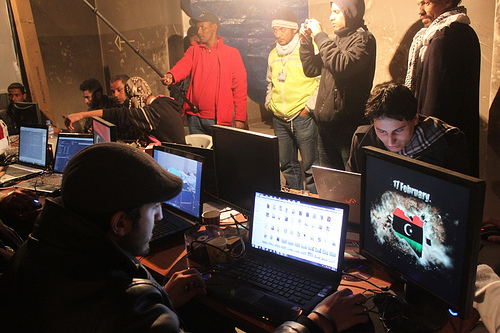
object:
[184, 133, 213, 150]
chair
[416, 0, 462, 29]
head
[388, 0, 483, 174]
person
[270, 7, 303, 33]
hat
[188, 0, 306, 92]
artwork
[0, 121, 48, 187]
laptop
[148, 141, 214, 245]
laptop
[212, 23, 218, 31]
ear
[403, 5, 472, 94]
scarf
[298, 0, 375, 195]
man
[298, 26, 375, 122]
sweater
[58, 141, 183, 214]
dark hat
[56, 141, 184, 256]
head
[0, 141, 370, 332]
man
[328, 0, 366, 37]
hat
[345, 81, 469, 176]
man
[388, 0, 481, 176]
man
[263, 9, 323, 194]
man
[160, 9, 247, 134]
man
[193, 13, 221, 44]
head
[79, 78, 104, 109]
head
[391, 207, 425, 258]
flag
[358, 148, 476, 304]
screen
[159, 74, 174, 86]
hand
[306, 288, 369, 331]
hand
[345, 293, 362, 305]
mouse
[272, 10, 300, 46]
head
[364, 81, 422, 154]
head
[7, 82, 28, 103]
head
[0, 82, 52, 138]
person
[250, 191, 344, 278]
screen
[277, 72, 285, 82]
hanging badge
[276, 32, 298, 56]
neck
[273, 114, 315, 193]
jeans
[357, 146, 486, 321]
monitor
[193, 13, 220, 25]
blue hat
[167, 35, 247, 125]
red jacket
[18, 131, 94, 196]
laptop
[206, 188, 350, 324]
laptop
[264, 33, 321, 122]
shirt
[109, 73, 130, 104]
head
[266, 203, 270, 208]
icon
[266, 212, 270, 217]
icon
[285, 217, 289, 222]
icon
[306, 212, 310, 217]
icon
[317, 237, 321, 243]
icon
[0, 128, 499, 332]
table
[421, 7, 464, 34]
neck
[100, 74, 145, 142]
person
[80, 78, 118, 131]
person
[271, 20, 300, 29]
band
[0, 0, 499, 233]
wall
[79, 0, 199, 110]
boom mic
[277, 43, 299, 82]
chain